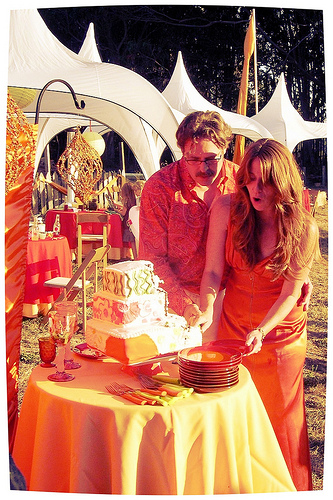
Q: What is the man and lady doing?
A: Cutting a cake.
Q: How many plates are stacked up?
A: Nine.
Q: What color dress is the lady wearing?
A: Orange.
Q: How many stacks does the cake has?
A: 3.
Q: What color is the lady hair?
A: Brown.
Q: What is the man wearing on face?
A: Glasses.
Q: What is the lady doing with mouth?
A: Open.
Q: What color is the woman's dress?
A: Orange.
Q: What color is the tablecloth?
A: Yellow.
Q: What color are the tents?
A: White.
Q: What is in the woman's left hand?
A: Plate.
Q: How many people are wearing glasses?
A: 1.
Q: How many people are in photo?
A: 2.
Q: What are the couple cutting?
A: Cake.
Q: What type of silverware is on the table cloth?
A: Fork.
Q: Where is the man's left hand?
A: Around woman's waist.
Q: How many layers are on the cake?
A: 3.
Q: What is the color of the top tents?
A: White.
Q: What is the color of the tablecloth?
A: White.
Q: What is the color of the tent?
A: White.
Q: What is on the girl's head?
A: Hair.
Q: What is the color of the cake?
A: White.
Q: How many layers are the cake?
A: 3.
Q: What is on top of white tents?
A: Points.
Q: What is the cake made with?
A: Icing.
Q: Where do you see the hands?
A: On cake.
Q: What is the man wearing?
A: Paisley shirt.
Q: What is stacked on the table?
A: Plates.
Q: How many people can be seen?
A: 2.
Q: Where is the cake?
A: On the table.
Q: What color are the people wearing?
A: Orange.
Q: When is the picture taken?
A: Daytime.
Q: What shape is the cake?
A: Square.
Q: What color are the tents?
A: White.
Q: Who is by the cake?
A: A man and woman.